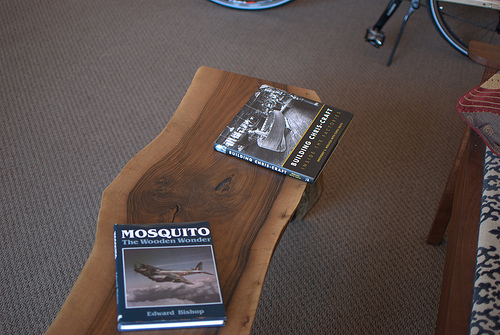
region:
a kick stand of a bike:
[389, 2, 423, 71]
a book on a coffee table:
[108, 207, 223, 333]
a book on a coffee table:
[211, 80, 358, 185]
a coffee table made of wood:
[41, 56, 325, 333]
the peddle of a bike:
[363, 2, 398, 50]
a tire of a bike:
[427, 1, 499, 58]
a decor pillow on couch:
[460, 65, 499, 155]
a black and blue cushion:
[471, 139, 498, 334]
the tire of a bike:
[198, 0, 293, 7]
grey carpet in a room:
[1, 0, 499, 334]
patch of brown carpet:
[326, 259, 353, 284]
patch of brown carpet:
[382, 280, 415, 312]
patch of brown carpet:
[42, 157, 83, 194]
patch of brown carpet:
[67, 121, 100, 146]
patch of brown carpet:
[45, 249, 70, 274]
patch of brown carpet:
[19, 127, 42, 151]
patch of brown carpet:
[372, 192, 411, 223]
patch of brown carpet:
[301, 307, 331, 324]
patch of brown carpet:
[368, 147, 400, 172]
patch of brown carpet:
[294, 290, 321, 317]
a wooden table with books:
[104, 73, 449, 333]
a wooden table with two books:
[119, 90, 357, 326]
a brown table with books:
[87, 88, 389, 333]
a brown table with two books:
[96, 73, 406, 326]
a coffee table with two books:
[87, 83, 362, 321]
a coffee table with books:
[84, 77, 496, 275]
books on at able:
[54, 39, 486, 329]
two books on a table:
[123, 69, 330, 334]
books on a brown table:
[166, 105, 383, 319]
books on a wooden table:
[84, 39, 351, 322]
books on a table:
[173, 73, 294, 148]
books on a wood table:
[157, 76, 377, 267]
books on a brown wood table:
[104, 61, 379, 226]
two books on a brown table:
[65, 66, 364, 333]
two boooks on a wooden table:
[97, 86, 454, 333]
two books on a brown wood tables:
[101, 83, 365, 322]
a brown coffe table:
[73, 61, 396, 319]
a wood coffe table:
[61, 61, 417, 333]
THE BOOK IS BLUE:
[97, 197, 232, 332]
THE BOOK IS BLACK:
[193, 80, 374, 190]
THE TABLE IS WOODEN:
[28, 58, 343, 333]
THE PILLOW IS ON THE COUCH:
[452, 56, 497, 148]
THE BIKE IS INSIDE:
[350, 0, 496, 90]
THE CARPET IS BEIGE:
[0, 0, 496, 332]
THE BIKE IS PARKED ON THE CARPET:
[202, 0, 497, 70]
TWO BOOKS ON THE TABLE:
[70, 80, 361, 333]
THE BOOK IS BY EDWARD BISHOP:
[100, 215, 247, 333]